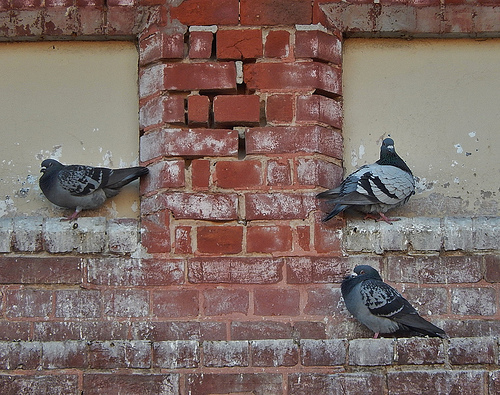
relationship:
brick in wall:
[215, 28, 262, 60] [138, 28, 343, 256]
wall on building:
[347, 40, 499, 226] [4, 0, 498, 392]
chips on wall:
[451, 128, 481, 170] [341, 34, 496, 218]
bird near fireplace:
[37, 157, 149, 224] [0, 2, 498, 394]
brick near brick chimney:
[165, 60, 249, 97] [139, 36, 345, 226]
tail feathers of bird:
[320, 188, 357, 223] [320, 137, 417, 224]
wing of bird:
[347, 163, 415, 209] [328, 139, 421, 219]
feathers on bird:
[288, 123, 428, 226] [319, 138, 431, 232]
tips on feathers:
[358, 171, 388, 202] [288, 123, 428, 226]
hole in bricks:
[223, 61, 261, 101] [168, 134, 248, 194]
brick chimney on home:
[139, 36, 345, 226] [7, 3, 489, 393]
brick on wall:
[210, 157, 269, 189] [5, 13, 492, 393]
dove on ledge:
[314, 131, 413, 227] [10, 176, 496, 381]